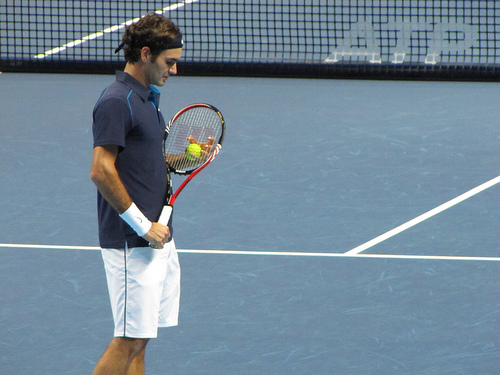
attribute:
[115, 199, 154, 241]
band — white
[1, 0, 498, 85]
tennis net — black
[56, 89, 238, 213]
top — blue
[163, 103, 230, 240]
racket — white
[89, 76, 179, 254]
shirt — blue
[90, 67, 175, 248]
polo shirt — navy blue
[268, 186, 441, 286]
lines — white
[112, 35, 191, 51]
headband — black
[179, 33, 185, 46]
design — white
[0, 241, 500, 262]
line — painted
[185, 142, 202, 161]
ball — bright green, tennis ball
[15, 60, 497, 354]
court — painted, green, tennis court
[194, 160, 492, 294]
lines — white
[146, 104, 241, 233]
racket — tennis racket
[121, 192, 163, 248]
wrist band — large, white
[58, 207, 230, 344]
shorts — white, tennis shorts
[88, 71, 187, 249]
shirt — tennis shirt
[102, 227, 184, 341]
shorts — tennis shorts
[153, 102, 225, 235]
tennis racket — black, red, white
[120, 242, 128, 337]
stripe — thin